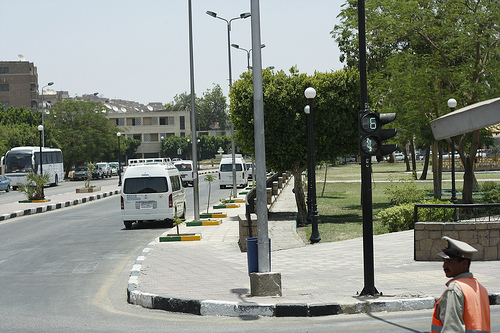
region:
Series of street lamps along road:
[179, 1, 266, 223]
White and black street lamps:
[287, 75, 464, 154]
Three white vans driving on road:
[115, 139, 246, 228]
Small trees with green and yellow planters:
[164, 186, 263, 248]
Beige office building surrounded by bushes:
[99, 111, 193, 158]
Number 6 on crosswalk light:
[353, 109, 388, 141]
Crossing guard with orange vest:
[401, 234, 497, 331]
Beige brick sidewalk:
[175, 242, 342, 297]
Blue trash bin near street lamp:
[239, 229, 287, 294]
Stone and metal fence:
[405, 189, 499, 257]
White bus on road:
[0, 139, 70, 194]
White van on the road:
[112, 159, 199, 235]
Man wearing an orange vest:
[420, 228, 498, 330]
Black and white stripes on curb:
[120, 261, 246, 330]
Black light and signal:
[338, 86, 408, 205]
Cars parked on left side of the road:
[65, 153, 132, 186]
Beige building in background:
[35, 81, 205, 183]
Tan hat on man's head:
[425, 226, 487, 292]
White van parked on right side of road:
[210, 153, 250, 197]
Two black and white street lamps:
[295, 88, 332, 253]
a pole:
[210, 134, 282, 236]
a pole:
[242, 85, 330, 303]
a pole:
[224, 165, 321, 316]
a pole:
[198, 80, 302, 310]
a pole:
[230, 142, 297, 284]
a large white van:
[119, 160, 185, 230]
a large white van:
[216, 154, 243, 190]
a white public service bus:
[5, 145, 63, 187]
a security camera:
[413, 94, 498, 148]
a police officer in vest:
[423, 233, 490, 331]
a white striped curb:
[126, 220, 151, 302]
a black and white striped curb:
[135, 286, 499, 314]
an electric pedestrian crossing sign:
[351, 108, 386, 159]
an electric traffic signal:
[377, 107, 402, 164]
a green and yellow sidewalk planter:
[157, 203, 200, 245]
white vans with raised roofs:
[117, 144, 248, 226]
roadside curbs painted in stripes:
[0, 174, 127, 243]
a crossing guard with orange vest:
[409, 229, 499, 331]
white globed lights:
[300, 66, 323, 247]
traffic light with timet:
[359, 95, 400, 169]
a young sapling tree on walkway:
[198, 166, 226, 225]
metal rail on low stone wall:
[410, 202, 499, 253]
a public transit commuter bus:
[2, 141, 70, 191]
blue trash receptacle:
[240, 226, 277, 287]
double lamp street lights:
[198, 4, 258, 219]